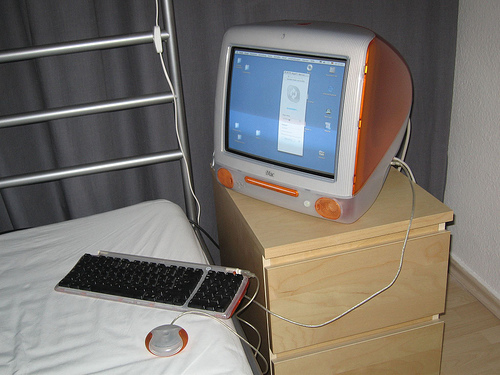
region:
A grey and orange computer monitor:
[203, 18, 418, 225]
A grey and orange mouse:
[145, 322, 188, 359]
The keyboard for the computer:
[53, 247, 250, 322]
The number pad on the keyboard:
[186, 266, 243, 320]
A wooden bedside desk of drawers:
[214, 168, 456, 373]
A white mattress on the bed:
[0, 194, 255, 373]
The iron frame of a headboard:
[3, 0, 198, 217]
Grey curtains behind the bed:
[5, 2, 459, 227]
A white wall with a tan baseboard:
[440, 0, 498, 307]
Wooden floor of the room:
[443, 271, 498, 373]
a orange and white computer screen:
[186, 14, 433, 276]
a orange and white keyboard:
[32, 223, 288, 338]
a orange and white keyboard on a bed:
[15, 207, 295, 358]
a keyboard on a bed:
[25, 212, 288, 339]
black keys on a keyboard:
[31, 221, 300, 337]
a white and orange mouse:
[122, 310, 212, 359]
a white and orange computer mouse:
[133, 319, 214, 364]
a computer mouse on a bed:
[77, 301, 225, 372]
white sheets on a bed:
[11, 219, 80, 360]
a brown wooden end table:
[210, 143, 498, 370]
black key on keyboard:
[90, 252, 103, 262]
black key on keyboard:
[79, 272, 93, 275]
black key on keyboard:
[95, 276, 114, 290]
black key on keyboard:
[115, 254, 137, 274]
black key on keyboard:
[130, 273, 155, 304]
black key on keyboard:
[166, 265, 181, 280]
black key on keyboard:
[165, 267, 192, 293]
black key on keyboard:
[213, 282, 233, 298]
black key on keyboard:
[190, 288, 214, 307]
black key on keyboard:
[163, 274, 183, 292]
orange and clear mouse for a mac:
[141, 316, 188, 362]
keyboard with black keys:
[51, 240, 246, 321]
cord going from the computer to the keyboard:
[233, 158, 425, 330]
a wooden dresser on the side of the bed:
[215, 165, 461, 373]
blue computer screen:
[211, 42, 361, 191]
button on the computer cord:
[147, 23, 168, 53]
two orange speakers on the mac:
[205, 160, 355, 232]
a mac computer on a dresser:
[204, 16, 415, 234]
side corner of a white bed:
[2, 199, 254, 371]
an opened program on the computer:
[275, 65, 310, 157]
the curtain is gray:
[417, 15, 454, 180]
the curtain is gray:
[40, 17, 142, 209]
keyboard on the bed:
[63, 237, 254, 325]